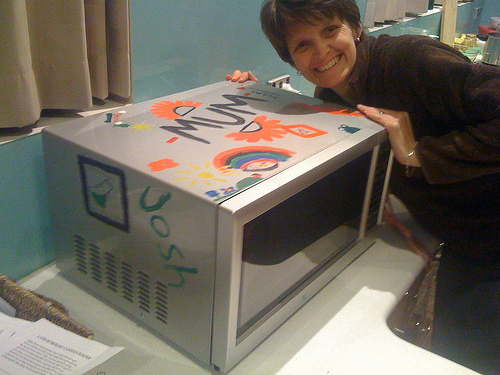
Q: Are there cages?
A: No, there are no cages.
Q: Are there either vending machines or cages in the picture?
A: No, there are no cages or vending machines.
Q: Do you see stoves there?
A: No, there are no stoves.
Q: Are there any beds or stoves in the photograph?
A: No, there are no stoves or beds.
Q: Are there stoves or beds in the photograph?
A: No, there are no stoves or beds.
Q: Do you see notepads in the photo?
A: No, there are no notepads.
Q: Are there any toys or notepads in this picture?
A: No, there are no notepads or toys.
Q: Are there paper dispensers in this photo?
A: No, there are no paper dispensers.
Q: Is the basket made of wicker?
A: Yes, the basket is made of wicker.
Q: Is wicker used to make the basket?
A: Yes, the basket is made of wicker.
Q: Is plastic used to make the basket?
A: No, the basket is made of wicker.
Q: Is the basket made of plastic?
A: No, the basket is made of wicker.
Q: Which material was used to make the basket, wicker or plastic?
A: The basket is made of wicker.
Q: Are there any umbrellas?
A: No, there are no umbrellas.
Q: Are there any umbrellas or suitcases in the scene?
A: No, there are no umbrellas or suitcases.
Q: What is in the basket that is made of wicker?
A: The paper is in the basket.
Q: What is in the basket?
A: The paper is in the basket.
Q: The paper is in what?
A: The paper is in the basket.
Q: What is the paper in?
A: The paper is in the basket.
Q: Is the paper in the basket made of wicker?
A: Yes, the paper is in the basket.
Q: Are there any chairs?
A: No, there are no chairs.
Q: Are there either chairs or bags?
A: No, there are no chairs or bags.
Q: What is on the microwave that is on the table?
A: The drawings are on the microwave.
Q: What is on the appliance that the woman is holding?
A: The drawings are on the microwave.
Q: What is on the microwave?
A: The drawings are on the microwave.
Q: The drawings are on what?
A: The drawings are on the microwave.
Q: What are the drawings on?
A: The drawings are on the microwave.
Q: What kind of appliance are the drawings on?
A: The drawings are on the microwave.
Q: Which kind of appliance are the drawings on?
A: The drawings are on the microwave.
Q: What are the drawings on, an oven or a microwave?
A: The drawings are on a microwave.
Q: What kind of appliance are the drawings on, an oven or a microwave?
A: The drawings are on a microwave.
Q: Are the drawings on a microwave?
A: Yes, the drawings are on a microwave.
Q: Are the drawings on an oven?
A: No, the drawings are on a microwave.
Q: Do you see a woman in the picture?
A: Yes, there is a woman.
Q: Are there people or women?
A: Yes, there is a woman.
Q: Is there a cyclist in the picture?
A: No, there are no cyclists.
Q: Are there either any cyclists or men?
A: No, there are no cyclists or men.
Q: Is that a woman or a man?
A: That is a woman.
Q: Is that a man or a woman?
A: That is a woman.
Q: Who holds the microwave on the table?
A: The woman holds the microwave.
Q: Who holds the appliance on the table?
A: The woman holds the microwave.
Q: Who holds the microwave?
A: The woman holds the microwave.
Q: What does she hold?
A: The woman holds the microwave.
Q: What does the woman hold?
A: The woman holds the microwave.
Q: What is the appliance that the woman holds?
A: The appliance is a microwave.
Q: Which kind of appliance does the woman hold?
A: The woman holds the microwave.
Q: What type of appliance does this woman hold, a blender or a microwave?
A: The woman holds a microwave.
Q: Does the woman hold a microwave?
A: Yes, the woman holds a microwave.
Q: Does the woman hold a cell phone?
A: No, the woman holds a microwave.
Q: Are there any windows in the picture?
A: Yes, there is a window.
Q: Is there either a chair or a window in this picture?
A: Yes, there is a window.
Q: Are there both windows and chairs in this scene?
A: No, there is a window but no chairs.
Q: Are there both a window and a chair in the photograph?
A: No, there is a window but no chairs.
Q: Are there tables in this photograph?
A: Yes, there is a table.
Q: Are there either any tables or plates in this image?
A: Yes, there is a table.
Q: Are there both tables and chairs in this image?
A: No, there is a table but no chairs.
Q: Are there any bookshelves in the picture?
A: No, there are no bookshelves.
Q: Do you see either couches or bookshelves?
A: No, there are no bookshelves or couches.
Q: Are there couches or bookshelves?
A: No, there are no bookshelves or couches.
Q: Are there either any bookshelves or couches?
A: No, there are no bookshelves or couches.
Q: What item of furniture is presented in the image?
A: The piece of furniture is a table.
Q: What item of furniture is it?
A: The piece of furniture is a table.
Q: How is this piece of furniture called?
A: This is a table.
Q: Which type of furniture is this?
A: This is a table.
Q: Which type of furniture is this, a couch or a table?
A: This is a table.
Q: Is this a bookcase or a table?
A: This is a table.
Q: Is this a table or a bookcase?
A: This is a table.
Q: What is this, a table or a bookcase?
A: This is a table.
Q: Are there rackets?
A: No, there are no rackets.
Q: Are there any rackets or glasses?
A: No, there are no rackets or glasses.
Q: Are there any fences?
A: No, there are no fences.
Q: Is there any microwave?
A: Yes, there is a microwave.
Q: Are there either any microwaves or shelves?
A: Yes, there is a microwave.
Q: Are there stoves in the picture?
A: No, there are no stoves.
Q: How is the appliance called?
A: The appliance is a microwave.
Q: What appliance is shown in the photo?
A: The appliance is a microwave.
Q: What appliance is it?
A: The appliance is a microwave.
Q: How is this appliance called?
A: This is a microwave.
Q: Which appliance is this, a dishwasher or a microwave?
A: This is a microwave.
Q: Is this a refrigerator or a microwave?
A: This is a microwave.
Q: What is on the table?
A: The microwave is on the table.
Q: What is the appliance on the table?
A: The appliance is a microwave.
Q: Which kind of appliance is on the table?
A: The appliance is a microwave.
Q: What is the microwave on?
A: The microwave is on the table.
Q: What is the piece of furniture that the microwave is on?
A: The piece of furniture is a table.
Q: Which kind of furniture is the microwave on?
A: The microwave is on the table.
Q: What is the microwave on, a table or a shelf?
A: The microwave is on a table.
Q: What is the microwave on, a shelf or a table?
A: The microwave is on a table.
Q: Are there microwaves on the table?
A: Yes, there is a microwave on the table.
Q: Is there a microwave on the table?
A: Yes, there is a microwave on the table.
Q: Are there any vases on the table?
A: No, there is a microwave on the table.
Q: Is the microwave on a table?
A: Yes, the microwave is on a table.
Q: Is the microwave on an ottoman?
A: No, the microwave is on a table.